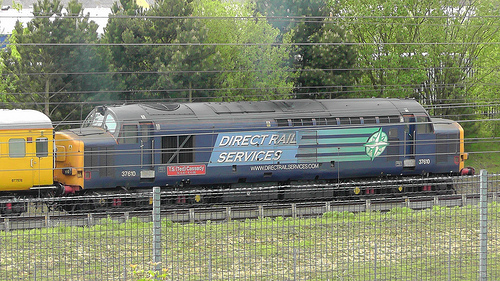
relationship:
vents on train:
[275, 115, 400, 125] [0, 88, 477, 222]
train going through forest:
[0, 88, 477, 222] [0, 2, 492, 184]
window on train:
[106, 121, 149, 157] [83, 100, 465, 188]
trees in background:
[401, 31, 465, 78] [3, 20, 498, 98]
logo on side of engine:
[203, 124, 391, 166] [62, 87, 474, 196]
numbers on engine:
[420, 159, 431, 165] [56, 96, 468, 208]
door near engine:
[400, 116, 417, 161] [427, 117, 462, 172]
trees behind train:
[1, 0, 498, 160] [0, 88, 477, 222]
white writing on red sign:
[168, 166, 201, 174] [162, 162, 210, 179]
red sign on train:
[162, 162, 210, 179] [0, 88, 477, 222]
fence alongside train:
[0, 204, 498, 278] [267, 96, 474, 200]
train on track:
[0, 88, 477, 222] [9, 200, 492, 229]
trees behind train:
[2, 21, 498, 143] [0, 88, 477, 222]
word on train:
[217, 133, 267, 145] [60, 97, 472, 182]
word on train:
[267, 131, 297, 143] [60, 97, 472, 182]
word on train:
[215, 150, 284, 163] [60, 97, 472, 182]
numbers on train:
[121, 168, 136, 177] [60, 97, 472, 182]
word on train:
[268, 133, 297, 144] [1, 92, 478, 212]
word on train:
[214, 147, 286, 165] [1, 92, 478, 212]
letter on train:
[219, 136, 229, 145] [1, 92, 478, 212]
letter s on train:
[215, 149, 227, 163] [61, 101, 463, 196]